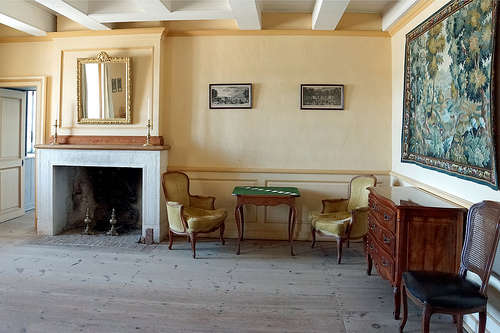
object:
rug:
[12, 259, 365, 333]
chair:
[161, 171, 228, 259]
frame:
[76, 51, 134, 125]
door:
[0, 88, 27, 224]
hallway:
[0, 209, 38, 232]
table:
[232, 186, 301, 256]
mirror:
[80, 62, 126, 121]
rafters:
[22, 50, 35, 54]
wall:
[166, 34, 389, 78]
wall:
[165, 117, 392, 164]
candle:
[148, 98, 151, 119]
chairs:
[308, 174, 377, 264]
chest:
[362, 186, 467, 320]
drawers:
[368, 194, 396, 274]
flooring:
[1, 263, 353, 331]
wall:
[0, 33, 54, 70]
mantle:
[33, 144, 160, 149]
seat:
[183, 206, 228, 230]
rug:
[400, 0, 500, 192]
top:
[232, 186, 300, 196]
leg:
[235, 202, 243, 248]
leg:
[240, 205, 245, 237]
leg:
[288, 206, 292, 238]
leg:
[291, 206, 297, 252]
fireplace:
[33, 144, 161, 244]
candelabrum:
[50, 120, 59, 146]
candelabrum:
[142, 119, 154, 147]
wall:
[390, 23, 403, 152]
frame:
[208, 83, 252, 109]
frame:
[299, 83, 344, 110]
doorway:
[1, 86, 36, 234]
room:
[1, 1, 480, 331]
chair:
[399, 200, 500, 333]